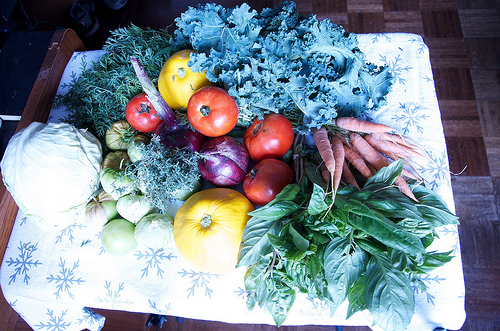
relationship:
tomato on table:
[242, 111, 295, 163] [5, 234, 82, 300]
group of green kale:
[215, 99, 293, 129] [250, 86, 307, 123]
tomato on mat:
[186, 85, 239, 137] [3, 16, 453, 300]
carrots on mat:
[305, 109, 432, 210] [19, 38, 465, 308]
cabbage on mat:
[0, 120, 105, 234] [3, 16, 453, 300]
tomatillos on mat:
[100, 152, 180, 262] [3, 16, 453, 300]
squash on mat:
[171, 185, 269, 277] [17, 35, 498, 326]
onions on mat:
[166, 136, 250, 185] [19, 38, 465, 308]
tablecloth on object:
[0, 32, 469, 330] [8, 28, 61, 128]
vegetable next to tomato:
[127, 54, 190, 134] [127, 92, 163, 133]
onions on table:
[196, 135, 249, 188] [17, 30, 493, 318]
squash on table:
[172, 187, 257, 276] [17, 30, 493, 318]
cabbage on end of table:
[0, 120, 105, 234] [17, 30, 493, 318]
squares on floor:
[438, 21, 496, 117] [446, 22, 487, 106]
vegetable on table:
[156, 48, 217, 112] [0, 30, 470, 329]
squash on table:
[172, 187, 257, 276] [0, 30, 470, 329]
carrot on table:
[333, 112, 398, 133] [0, 30, 470, 329]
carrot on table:
[313, 120, 337, 188] [0, 30, 470, 329]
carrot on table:
[327, 129, 346, 220] [0, 30, 470, 329]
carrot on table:
[343, 148, 371, 179] [0, 30, 470, 329]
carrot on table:
[343, 131, 420, 201] [0, 30, 470, 329]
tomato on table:
[242, 158, 294, 208] [0, 30, 470, 329]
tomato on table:
[242, 111, 295, 163] [0, 30, 470, 329]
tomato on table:
[186, 85, 239, 137] [0, 30, 470, 329]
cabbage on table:
[0, 120, 105, 234] [0, 30, 470, 329]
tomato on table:
[124, 92, 164, 133] [0, 30, 470, 329]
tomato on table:
[183, 82, 243, 132] [0, 30, 470, 329]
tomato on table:
[122, 90, 160, 130] [0, 30, 470, 329]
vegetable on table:
[153, 43, 214, 112] [0, 30, 470, 329]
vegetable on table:
[102, 212, 142, 255] [0, 30, 470, 329]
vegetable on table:
[111, 190, 160, 220] [0, 30, 470, 329]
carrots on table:
[314, 111, 427, 210] [0, 30, 470, 329]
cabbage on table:
[0, 118, 107, 223] [0, 30, 470, 329]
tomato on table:
[240, 150, 291, 197] [0, 30, 470, 329]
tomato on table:
[245, 109, 291, 163] [0, 30, 470, 329]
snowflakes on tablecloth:
[47, 253, 101, 299] [12, 39, 260, 324]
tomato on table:
[242, 158, 294, 208] [116, 260, 190, 306]